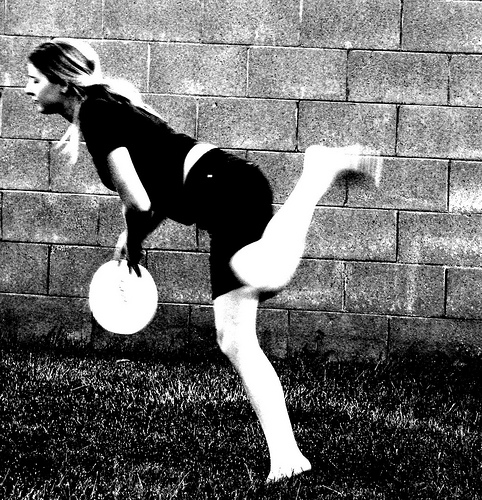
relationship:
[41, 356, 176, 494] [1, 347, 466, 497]
grass on ground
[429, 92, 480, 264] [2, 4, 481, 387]
chalk on wall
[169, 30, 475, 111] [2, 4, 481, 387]
tiles on wall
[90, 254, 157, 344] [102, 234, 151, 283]
frisbee in hand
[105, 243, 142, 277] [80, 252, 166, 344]
fingers on frisbee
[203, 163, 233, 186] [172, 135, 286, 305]
spot on shorts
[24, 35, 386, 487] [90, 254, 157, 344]
person holding plate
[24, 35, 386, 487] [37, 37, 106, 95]
person has hair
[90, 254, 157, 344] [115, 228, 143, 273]
frisbee in hand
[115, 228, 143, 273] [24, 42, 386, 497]
hand of person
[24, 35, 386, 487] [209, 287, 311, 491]
person standing on leg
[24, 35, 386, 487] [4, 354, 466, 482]
person standing in grass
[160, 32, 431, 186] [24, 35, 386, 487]
wall behind person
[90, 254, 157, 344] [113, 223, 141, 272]
frisbee in hand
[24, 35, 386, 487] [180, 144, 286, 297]
person wearing shorts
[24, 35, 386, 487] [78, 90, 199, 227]
person wearing clothing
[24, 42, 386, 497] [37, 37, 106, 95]
person has hair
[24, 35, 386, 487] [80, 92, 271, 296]
person wearing clothing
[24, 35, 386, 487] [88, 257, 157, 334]
person holding frisbee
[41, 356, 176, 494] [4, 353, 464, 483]
grass on ground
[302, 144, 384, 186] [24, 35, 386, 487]
foot of person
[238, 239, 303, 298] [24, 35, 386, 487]
knee of person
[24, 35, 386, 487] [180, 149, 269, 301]
person wearing shorts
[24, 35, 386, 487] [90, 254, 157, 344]
person holding frisbee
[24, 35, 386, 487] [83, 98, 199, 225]
person wearing shirt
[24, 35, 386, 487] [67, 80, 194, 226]
person wearing shirt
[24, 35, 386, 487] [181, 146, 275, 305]
person wearing shorts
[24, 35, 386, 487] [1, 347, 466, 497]
person bent over off ground